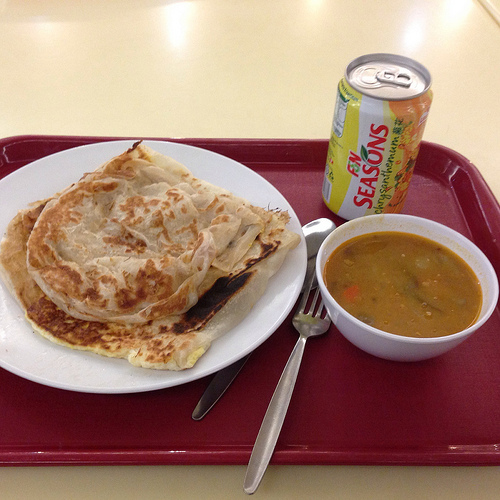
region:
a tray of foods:
[60, 112, 465, 495]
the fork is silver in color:
[267, 307, 324, 490]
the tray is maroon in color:
[0, 326, 499, 451]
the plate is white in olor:
[55, 277, 240, 374]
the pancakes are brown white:
[18, 196, 278, 305]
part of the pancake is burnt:
[170, 265, 249, 329]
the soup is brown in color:
[357, 245, 496, 294]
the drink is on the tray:
[335, 63, 420, 204]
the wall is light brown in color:
[68, 13, 234, 108]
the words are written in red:
[355, 119, 395, 203]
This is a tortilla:
[34, 154, 208, 362]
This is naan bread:
[75, 258, 265, 490]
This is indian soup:
[323, 242, 483, 402]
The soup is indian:
[297, 229, 467, 414]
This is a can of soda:
[305, 164, 400, 196]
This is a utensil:
[267, 347, 340, 484]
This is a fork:
[203, 419, 327, 489]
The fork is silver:
[241, 410, 293, 470]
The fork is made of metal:
[234, 404, 314, 498]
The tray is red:
[341, 392, 420, 480]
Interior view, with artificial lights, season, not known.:
[4, 11, 496, 495]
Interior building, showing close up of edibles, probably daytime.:
[2, 2, 497, 489]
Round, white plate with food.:
[3, 156, 269, 401]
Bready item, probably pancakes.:
[29, 176, 256, 363]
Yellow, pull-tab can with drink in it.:
[325, 52, 430, 213]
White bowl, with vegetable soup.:
[325, 217, 492, 356]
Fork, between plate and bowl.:
[246, 283, 326, 483]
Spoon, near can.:
[287, 207, 326, 260]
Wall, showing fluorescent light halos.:
[23, 10, 469, 63]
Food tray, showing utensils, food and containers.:
[4, 69, 468, 478]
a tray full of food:
[35, 97, 422, 498]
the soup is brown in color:
[333, 247, 480, 357]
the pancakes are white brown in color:
[74, 187, 236, 311]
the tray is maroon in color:
[306, 363, 474, 453]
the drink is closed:
[310, 52, 435, 205]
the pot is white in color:
[358, 303, 491, 358]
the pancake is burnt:
[178, 275, 255, 332]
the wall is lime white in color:
[171, 20, 316, 139]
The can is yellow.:
[308, 55, 425, 213]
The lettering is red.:
[337, 126, 383, 208]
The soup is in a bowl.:
[312, 205, 492, 357]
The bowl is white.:
[308, 218, 497, 353]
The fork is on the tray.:
[244, 299, 351, 490]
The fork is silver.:
[224, 269, 327, 498]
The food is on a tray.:
[12, 126, 497, 438]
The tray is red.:
[1, 127, 498, 474]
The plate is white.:
[6, 148, 318, 398]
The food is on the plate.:
[6, 155, 309, 372]